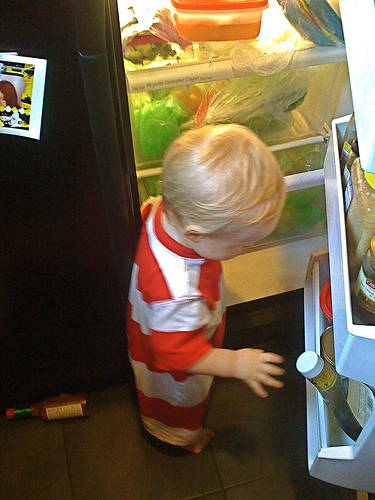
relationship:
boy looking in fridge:
[124, 123, 288, 455] [2, 3, 373, 498]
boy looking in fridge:
[124, 123, 288, 455] [101, 0, 374, 495]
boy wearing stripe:
[124, 123, 288, 455] [132, 224, 180, 304]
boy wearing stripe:
[124, 123, 288, 455] [117, 301, 211, 384]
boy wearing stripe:
[124, 123, 288, 455] [132, 385, 208, 428]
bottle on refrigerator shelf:
[288, 343, 373, 439] [300, 251, 373, 486]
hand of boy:
[233, 347, 286, 398] [124, 123, 288, 455]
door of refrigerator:
[299, 0, 375, 496] [73, 0, 374, 497]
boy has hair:
[128, 123, 287, 455] [155, 124, 274, 215]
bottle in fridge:
[295, 349, 374, 442] [72, 0, 374, 495]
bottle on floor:
[5, 391, 87, 425] [7, 326, 360, 492]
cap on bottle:
[288, 348, 319, 383] [295, 349, 374, 442]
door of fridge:
[315, 130, 371, 246] [101, 0, 374, 495]